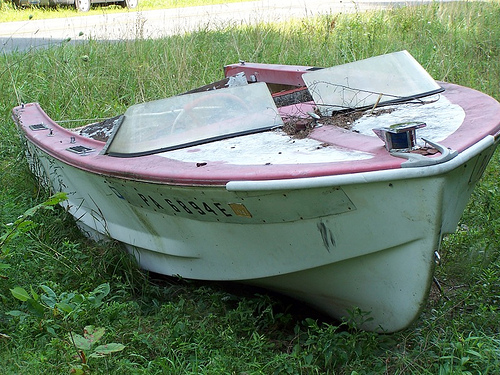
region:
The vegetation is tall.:
[0, 15, 497, 371]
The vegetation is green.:
[1, 12, 496, 368]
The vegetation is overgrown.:
[0, 46, 495, 371]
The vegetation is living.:
[1, 17, 496, 370]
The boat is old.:
[11, 41, 499, 356]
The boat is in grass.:
[13, 37, 498, 352]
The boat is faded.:
[2, 0, 497, 372]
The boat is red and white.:
[0, 48, 498, 353]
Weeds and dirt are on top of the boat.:
[277, 68, 419, 155]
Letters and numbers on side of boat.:
[105, 180, 265, 233]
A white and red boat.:
[12, 50, 499, 335]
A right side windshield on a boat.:
[302, 49, 441, 116]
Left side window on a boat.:
[102, 79, 284, 158]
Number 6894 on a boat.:
[162, 194, 217, 216]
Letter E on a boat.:
[213, 203, 231, 217]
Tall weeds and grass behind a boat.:
[45, 42, 179, 97]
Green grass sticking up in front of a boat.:
[299, 311, 376, 372]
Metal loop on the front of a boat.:
[432, 251, 441, 266]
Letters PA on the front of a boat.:
[135, 191, 162, 213]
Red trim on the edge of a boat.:
[11, 101, 428, 187]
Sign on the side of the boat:
[131, 179, 256, 228]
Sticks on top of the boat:
[281, 89, 372, 145]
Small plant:
[38, 280, 118, 367]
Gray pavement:
[7, 9, 349, 57]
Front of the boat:
[329, 173, 470, 341]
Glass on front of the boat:
[98, 87, 298, 157]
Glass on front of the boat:
[297, 53, 436, 116]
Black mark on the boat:
[307, 215, 342, 256]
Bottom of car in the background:
[5, 2, 146, 17]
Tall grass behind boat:
[42, 21, 489, 59]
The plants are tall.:
[10, 254, 91, 372]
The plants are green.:
[0, 254, 105, 373]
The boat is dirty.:
[51, 60, 460, 275]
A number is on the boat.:
[103, 176, 270, 240]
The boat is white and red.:
[8, 68, 488, 338]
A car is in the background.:
[11, 0, 156, 22]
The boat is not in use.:
[14, 45, 498, 345]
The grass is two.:
[36, 53, 139, 103]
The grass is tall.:
[31, 50, 190, 88]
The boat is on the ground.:
[5, 51, 496, 348]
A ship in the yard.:
[11, 38, 498, 342]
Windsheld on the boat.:
[108, 44, 448, 159]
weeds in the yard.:
[13, 279, 130, 373]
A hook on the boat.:
[428, 245, 443, 267]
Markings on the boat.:
[104, 183, 259, 232]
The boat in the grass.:
[185, 285, 499, 374]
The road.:
[5, 10, 297, 52]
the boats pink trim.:
[10, 83, 498, 184]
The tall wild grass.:
[45, 19, 230, 98]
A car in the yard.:
[10, 0, 151, 9]